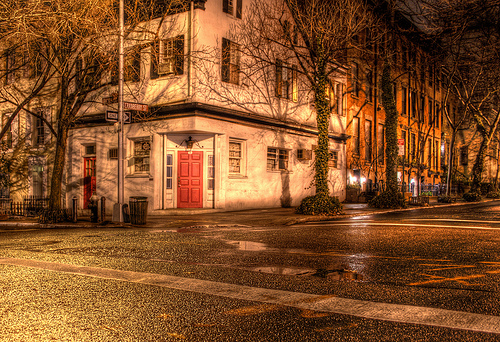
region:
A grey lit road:
[355, 218, 497, 339]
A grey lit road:
[197, 257, 354, 340]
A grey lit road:
[11, 255, 84, 340]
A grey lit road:
[52, 225, 294, 282]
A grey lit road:
[420, 196, 498, 247]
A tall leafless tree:
[261, 0, 345, 238]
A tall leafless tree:
[336, 0, 422, 202]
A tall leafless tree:
[406, 5, 463, 206]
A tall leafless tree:
[449, 0, 499, 205]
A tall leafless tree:
[0, 3, 121, 240]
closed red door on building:
[172, 147, 212, 216]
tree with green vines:
[311, 54, 347, 216]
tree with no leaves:
[12, 9, 98, 153]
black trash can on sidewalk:
[126, 191, 160, 238]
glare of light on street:
[347, 194, 381, 284]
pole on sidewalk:
[103, 6, 130, 231]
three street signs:
[100, 92, 153, 131]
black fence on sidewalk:
[8, 196, 71, 224]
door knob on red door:
[175, 171, 185, 192]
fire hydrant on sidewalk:
[82, 187, 107, 235]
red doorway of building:
[174, 138, 207, 216]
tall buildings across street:
[27, 9, 499, 274]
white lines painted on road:
[148, 245, 493, 329]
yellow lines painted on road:
[412, 192, 479, 249]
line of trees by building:
[306, 52, 495, 192]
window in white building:
[223, 135, 255, 187]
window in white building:
[256, 141, 292, 173]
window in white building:
[322, 149, 338, 174]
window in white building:
[215, 37, 252, 82]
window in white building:
[268, 53, 303, 98]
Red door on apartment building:
[177, 147, 205, 201]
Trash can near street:
[127, 195, 149, 223]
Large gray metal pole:
[115, 1, 124, 231]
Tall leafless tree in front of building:
[232, 0, 362, 212]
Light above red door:
[177, 135, 208, 148]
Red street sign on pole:
[122, 99, 152, 109]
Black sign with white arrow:
[107, 108, 130, 121]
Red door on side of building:
[81, 145, 104, 207]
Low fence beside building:
[13, 193, 57, 213]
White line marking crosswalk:
[9, 259, 496, 336]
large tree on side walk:
[282, 28, 364, 235]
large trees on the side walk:
[19, 13, 91, 239]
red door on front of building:
[165, 154, 210, 208]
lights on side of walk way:
[352, 156, 380, 190]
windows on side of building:
[100, 30, 247, 88]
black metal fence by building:
[8, 189, 45, 220]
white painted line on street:
[143, 248, 400, 337]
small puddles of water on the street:
[5, 223, 123, 276]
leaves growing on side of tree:
[303, 105, 345, 216]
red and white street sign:
[389, 127, 416, 160]